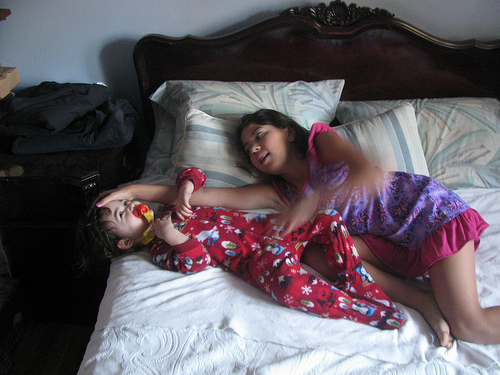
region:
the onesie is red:
[144, 171, 387, 334]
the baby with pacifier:
[66, 163, 183, 254]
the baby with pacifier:
[68, 189, 205, 281]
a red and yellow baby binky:
[130, 202, 151, 222]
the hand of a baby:
[152, 213, 174, 235]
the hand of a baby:
[172, 193, 194, 223]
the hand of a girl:
[96, 184, 134, 206]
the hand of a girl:
[271, 195, 314, 237]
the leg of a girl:
[430, 245, 498, 342]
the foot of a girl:
[414, 288, 448, 350]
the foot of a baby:
[358, 300, 405, 328]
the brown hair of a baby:
[81, 198, 116, 238]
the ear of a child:
[115, 232, 131, 247]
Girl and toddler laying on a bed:
[84, 108, 499, 347]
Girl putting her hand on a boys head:
[89, 108, 499, 353]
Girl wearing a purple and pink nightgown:
[93, 105, 498, 349]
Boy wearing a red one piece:
[83, 166, 407, 331]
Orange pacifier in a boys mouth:
[132, 202, 158, 245]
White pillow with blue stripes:
[164, 103, 430, 202]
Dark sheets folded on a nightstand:
[4, 80, 139, 155]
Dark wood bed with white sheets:
[75, 2, 497, 372]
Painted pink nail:
[93, 197, 105, 211]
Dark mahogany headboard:
[130, 3, 497, 106]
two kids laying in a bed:
[85, 110, 499, 345]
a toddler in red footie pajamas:
[91, 166, 402, 328]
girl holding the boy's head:
[98, 100, 498, 341]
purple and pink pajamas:
[300, 125, 486, 271]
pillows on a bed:
[155, 80, 497, 200]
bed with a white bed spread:
[73, 2, 495, 372]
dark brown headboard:
[135, 6, 495, 107]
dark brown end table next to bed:
[0, 152, 121, 292]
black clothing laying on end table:
[2, 80, 127, 153]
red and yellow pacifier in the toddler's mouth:
[132, 202, 153, 244]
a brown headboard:
[130, 4, 498, 144]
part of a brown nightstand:
[1, 143, 114, 308]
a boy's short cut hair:
[86, 202, 138, 259]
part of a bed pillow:
[149, 80, 345, 131]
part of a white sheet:
[91, 253, 493, 368]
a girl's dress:
[277, 127, 492, 262]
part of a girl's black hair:
[228, 110, 312, 161]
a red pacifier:
[130, 202, 147, 218]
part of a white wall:
[45, 0, 199, 26]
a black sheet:
[0, 79, 112, 138]